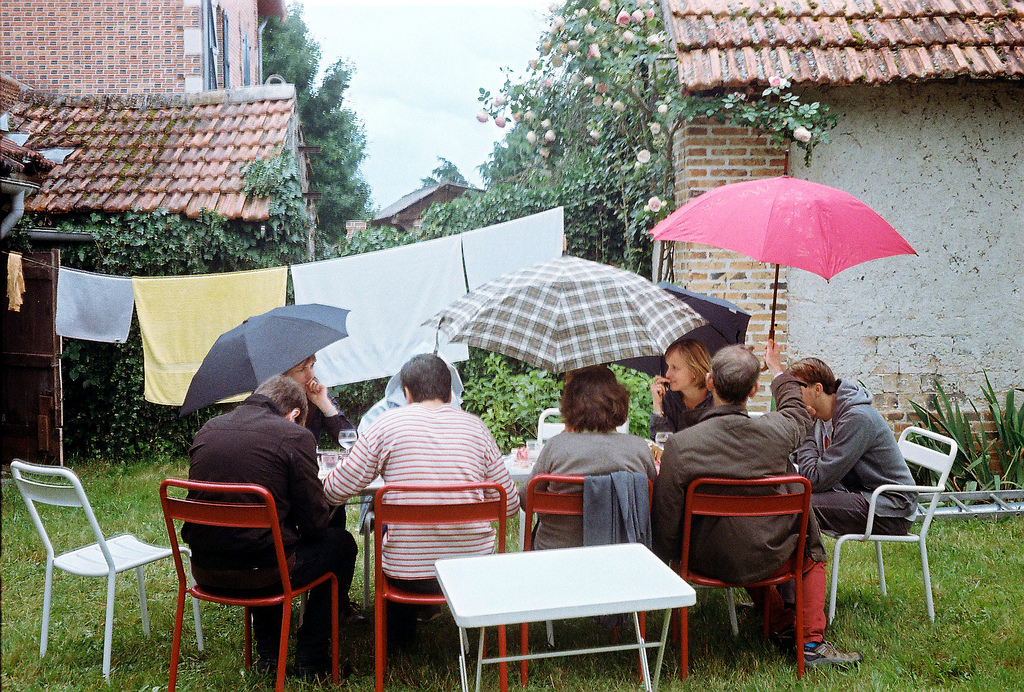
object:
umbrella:
[178, 304, 350, 418]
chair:
[9, 458, 192, 689]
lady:
[520, 365, 657, 550]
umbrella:
[643, 177, 919, 285]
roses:
[476, 0, 841, 216]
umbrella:
[422, 256, 706, 375]